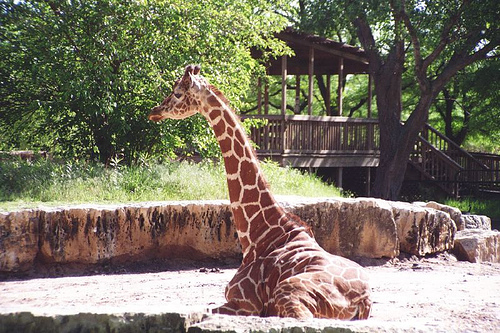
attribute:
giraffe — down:
[137, 67, 388, 320]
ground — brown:
[134, 58, 387, 318]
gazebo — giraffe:
[234, 17, 499, 210]